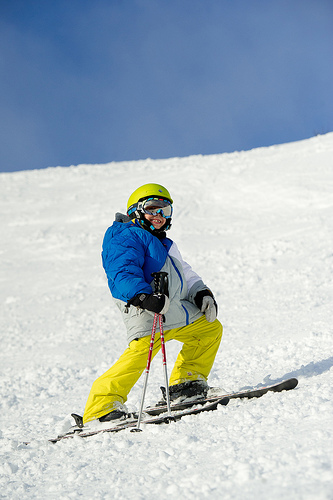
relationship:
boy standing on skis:
[80, 183, 223, 430] [50, 377, 298, 444]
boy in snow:
[80, 183, 223, 430] [1, 131, 332, 499]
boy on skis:
[80, 183, 223, 430] [50, 377, 298, 444]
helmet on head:
[125, 183, 174, 208] [124, 182, 175, 232]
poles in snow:
[130, 312, 174, 431] [1, 131, 332, 499]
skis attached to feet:
[50, 377, 298, 444] [88, 382, 216, 430]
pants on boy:
[81, 313, 223, 421] [80, 183, 223, 430]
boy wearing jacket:
[80, 183, 223, 430] [100, 214, 217, 343]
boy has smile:
[80, 183, 223, 430] [152, 217, 165, 227]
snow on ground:
[1, 131, 332, 499] [2, 131, 331, 500]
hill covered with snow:
[1, 128, 332, 498] [1, 131, 332, 499]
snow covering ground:
[1, 131, 332, 499] [2, 131, 331, 500]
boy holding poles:
[80, 183, 223, 430] [130, 312, 174, 431]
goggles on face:
[139, 197, 172, 213] [139, 196, 173, 231]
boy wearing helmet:
[80, 183, 223, 430] [125, 183, 174, 208]